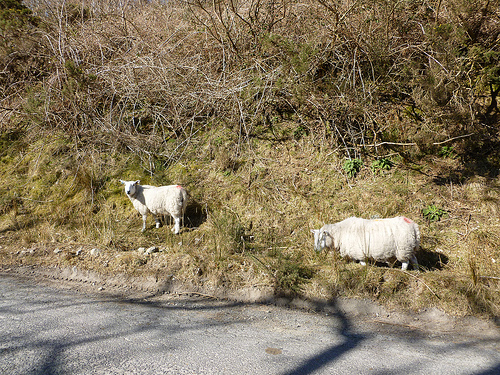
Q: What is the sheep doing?
A: Sniffing.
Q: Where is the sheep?
A: On the grass.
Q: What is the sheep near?
A: Road.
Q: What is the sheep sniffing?
A: Grass.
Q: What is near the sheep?
A: Road.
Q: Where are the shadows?
A: Near the sheep.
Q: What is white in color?
A: Sheep.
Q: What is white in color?
A: Sheep.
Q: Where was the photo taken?
A: On a road.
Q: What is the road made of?
A: Asphalt.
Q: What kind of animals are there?
A: Sheep.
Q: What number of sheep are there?
A: Two.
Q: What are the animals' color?
A: White.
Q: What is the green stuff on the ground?
A: Grass.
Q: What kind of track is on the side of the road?
A: A tire track.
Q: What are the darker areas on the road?
A: Shadows.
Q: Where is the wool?
A: On the sheep.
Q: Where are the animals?
A: In the field.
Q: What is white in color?
A: The animals.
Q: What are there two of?
A: Animals.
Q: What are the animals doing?
A: Walking.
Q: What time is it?
A: Afternoon.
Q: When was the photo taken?
A: During the daytime.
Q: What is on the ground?
A: Shadows.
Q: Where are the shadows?
A: On the ground.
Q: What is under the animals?
A: The ground.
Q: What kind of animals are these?
A: Sheep.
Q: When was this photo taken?
A: During the day.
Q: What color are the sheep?
A: White.